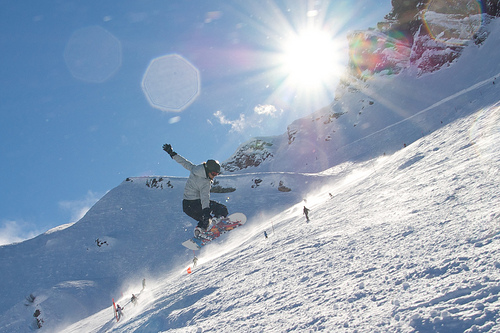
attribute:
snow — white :
[321, 190, 420, 296]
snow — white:
[34, 94, 473, 331]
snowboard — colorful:
[193, 212, 255, 239]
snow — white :
[146, 210, 471, 321]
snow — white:
[0, 10, 499, 330]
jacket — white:
[167, 148, 223, 218]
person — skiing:
[301, 202, 313, 223]